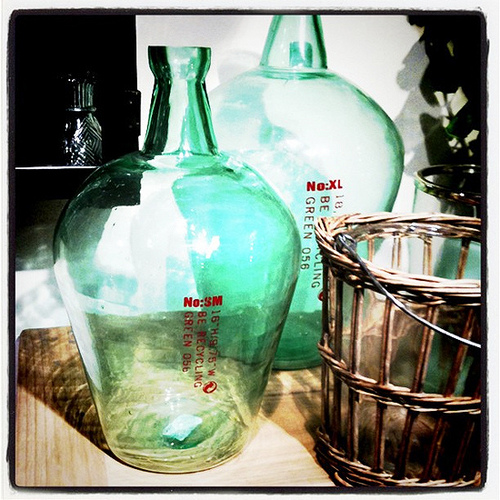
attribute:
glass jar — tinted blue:
[183, 14, 401, 371]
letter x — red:
[325, 175, 337, 192]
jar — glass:
[179, 11, 403, 368]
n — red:
[308, 180, 313, 192]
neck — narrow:
[144, 45, 223, 153]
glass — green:
[45, 118, 323, 471]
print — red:
[300, 181, 345, 303]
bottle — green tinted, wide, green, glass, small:
[53, 43, 298, 475]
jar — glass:
[65, 82, 292, 443]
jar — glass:
[47, 44, 302, 476]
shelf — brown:
[18, 146, 125, 181]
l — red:
[335, 175, 345, 192]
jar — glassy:
[217, 11, 410, 376]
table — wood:
[37, 329, 337, 494]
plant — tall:
[373, 22, 483, 235]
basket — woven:
[308, 195, 487, 475]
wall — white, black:
[322, 12, 424, 128]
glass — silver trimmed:
[45, 58, 330, 490]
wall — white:
[141, 23, 456, 309]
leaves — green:
[406, 12, 487, 217]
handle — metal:
[338, 229, 480, 355]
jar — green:
[39, 47, 311, 382]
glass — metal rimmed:
[406, 182, 444, 211]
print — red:
[175, 294, 229, 399]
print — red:
[303, 166, 358, 294]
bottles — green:
[106, 15, 369, 462]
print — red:
[178, 294, 221, 394]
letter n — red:
[182, 294, 193, 308]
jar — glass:
[55, 86, 300, 482]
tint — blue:
[178, 52, 306, 470]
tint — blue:
[55, 10, 403, 483]